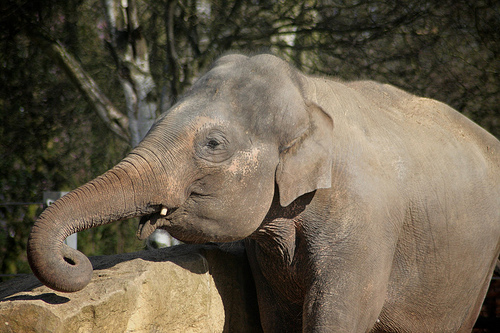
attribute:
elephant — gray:
[23, 52, 499, 332]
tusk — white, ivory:
[160, 204, 168, 216]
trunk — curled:
[23, 143, 169, 294]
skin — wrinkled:
[25, 50, 498, 330]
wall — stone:
[1, 244, 259, 332]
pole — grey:
[40, 188, 79, 256]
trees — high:
[44, 0, 312, 250]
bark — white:
[49, 0, 323, 248]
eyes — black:
[206, 136, 220, 149]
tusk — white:
[159, 204, 169, 217]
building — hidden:
[0, 0, 497, 275]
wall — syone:
[7, 238, 236, 330]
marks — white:
[224, 141, 267, 181]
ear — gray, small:
[274, 108, 336, 205]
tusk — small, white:
[154, 203, 175, 218]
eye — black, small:
[195, 136, 225, 158]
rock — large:
[1, 241, 251, 331]